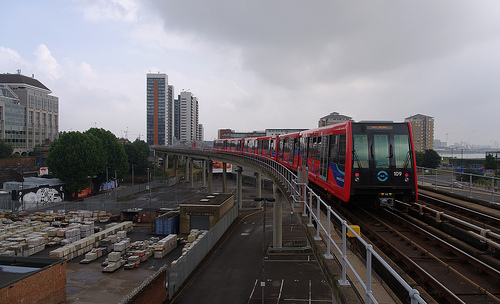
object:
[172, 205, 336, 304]
parking area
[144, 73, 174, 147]
building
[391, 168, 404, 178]
number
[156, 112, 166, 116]
windows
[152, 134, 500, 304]
bridge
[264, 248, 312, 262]
spaces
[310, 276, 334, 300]
spaces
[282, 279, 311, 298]
spaces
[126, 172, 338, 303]
pavement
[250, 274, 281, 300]
spaces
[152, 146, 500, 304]
track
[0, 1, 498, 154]
clouds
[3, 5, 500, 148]
sky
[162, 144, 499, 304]
fence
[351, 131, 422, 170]
window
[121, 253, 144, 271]
cars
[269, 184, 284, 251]
pillar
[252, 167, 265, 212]
pillar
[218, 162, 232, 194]
pillar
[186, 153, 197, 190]
pillar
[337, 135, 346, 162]
part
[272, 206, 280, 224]
part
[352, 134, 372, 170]
part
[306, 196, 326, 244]
railing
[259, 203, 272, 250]
light pole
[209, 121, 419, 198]
red paint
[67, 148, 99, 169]
leaves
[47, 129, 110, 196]
tree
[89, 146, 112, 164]
leaves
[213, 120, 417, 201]
train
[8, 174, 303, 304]
street